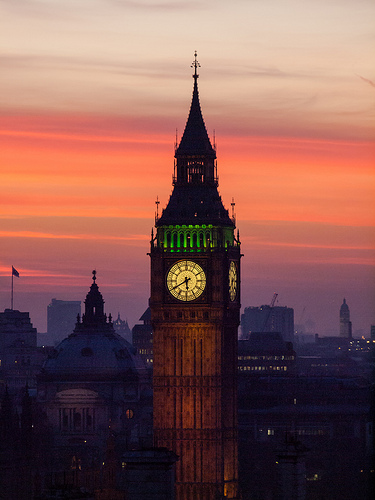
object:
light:
[176, 232, 181, 247]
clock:
[167, 259, 209, 304]